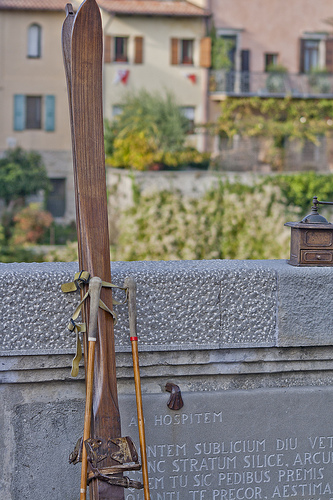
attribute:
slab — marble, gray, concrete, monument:
[3, 261, 331, 498]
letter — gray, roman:
[24, 385, 331, 494]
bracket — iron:
[159, 378, 184, 410]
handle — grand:
[125, 280, 150, 499]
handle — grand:
[75, 276, 101, 499]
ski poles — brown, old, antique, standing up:
[71, 1, 123, 500]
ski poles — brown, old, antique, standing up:
[61, 16, 72, 154]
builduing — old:
[205, 5, 329, 264]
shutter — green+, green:
[42, 96, 57, 133]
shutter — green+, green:
[12, 93, 31, 132]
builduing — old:
[2, 5, 211, 260]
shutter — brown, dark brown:
[199, 39, 214, 73]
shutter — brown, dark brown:
[166, 38, 184, 67]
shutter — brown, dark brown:
[132, 35, 146, 63]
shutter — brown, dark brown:
[98, 34, 117, 64]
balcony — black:
[214, 71, 330, 104]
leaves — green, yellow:
[118, 178, 286, 263]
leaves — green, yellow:
[110, 108, 189, 167]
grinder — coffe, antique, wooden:
[293, 205, 332, 266]